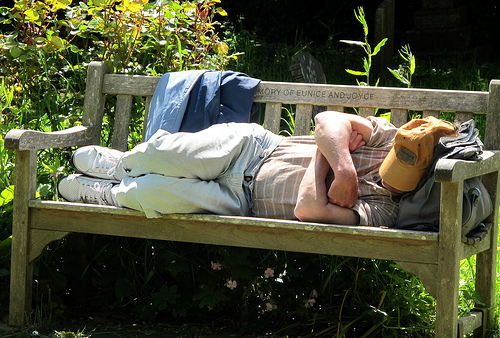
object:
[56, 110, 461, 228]
man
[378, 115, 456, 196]
hat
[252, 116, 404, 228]
shirt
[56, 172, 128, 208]
shoes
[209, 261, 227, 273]
flowers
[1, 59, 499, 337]
bench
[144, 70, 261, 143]
jacket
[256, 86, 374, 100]
writing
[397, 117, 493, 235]
bag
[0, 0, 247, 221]
bush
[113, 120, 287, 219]
jeans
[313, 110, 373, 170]
arms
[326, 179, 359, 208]
hands